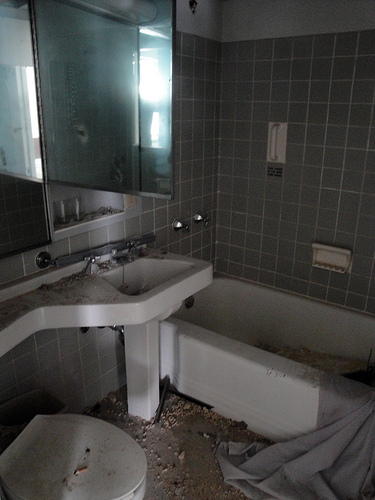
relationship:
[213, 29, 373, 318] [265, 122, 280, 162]
wall has a bar attached bar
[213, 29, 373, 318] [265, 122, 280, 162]
wall has gray tiles bar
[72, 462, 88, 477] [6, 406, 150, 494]
cigarette on lid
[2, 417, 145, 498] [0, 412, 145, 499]
cover on toilet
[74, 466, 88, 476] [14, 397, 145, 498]
cigarette on toilet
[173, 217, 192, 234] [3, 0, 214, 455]
handle on wall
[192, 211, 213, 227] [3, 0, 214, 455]
handle on wall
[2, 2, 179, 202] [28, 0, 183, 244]
mirror on cabinet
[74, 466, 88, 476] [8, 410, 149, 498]
cigarette on lid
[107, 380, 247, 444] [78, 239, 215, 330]
debris surrounding sink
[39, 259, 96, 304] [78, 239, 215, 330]
debris surrounding sink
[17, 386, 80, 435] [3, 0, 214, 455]
trash can against wall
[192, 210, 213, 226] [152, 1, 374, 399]
knob in shower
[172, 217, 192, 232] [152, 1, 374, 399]
knob in shower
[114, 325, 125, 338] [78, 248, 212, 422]
pipe behind sink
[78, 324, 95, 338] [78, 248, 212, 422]
pipe behind sink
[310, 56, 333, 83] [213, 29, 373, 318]
tile in wall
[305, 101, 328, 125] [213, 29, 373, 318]
tile in wall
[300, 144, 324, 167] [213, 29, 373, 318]
tile in wall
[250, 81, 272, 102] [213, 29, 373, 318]
tile in wall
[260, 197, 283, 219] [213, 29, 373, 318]
tile in wall